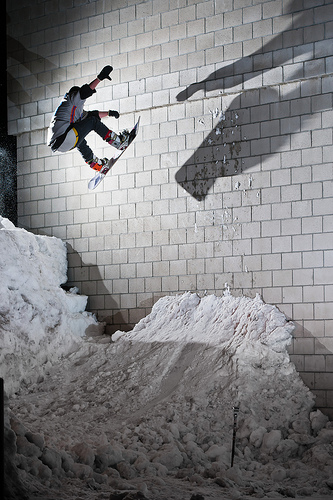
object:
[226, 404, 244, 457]
pole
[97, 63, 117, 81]
glove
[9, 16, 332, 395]
brick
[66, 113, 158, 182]
snow board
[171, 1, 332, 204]
shadow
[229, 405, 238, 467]
stick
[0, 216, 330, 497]
snow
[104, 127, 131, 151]
boot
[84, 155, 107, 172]
boot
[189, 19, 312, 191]
shadow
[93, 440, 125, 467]
clump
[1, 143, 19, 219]
tree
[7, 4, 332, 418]
building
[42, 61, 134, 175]
snowboarder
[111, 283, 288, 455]
ramp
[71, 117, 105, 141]
gray pants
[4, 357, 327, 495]
ground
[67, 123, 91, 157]
belt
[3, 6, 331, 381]
wall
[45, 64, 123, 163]
man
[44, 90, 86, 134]
shirt